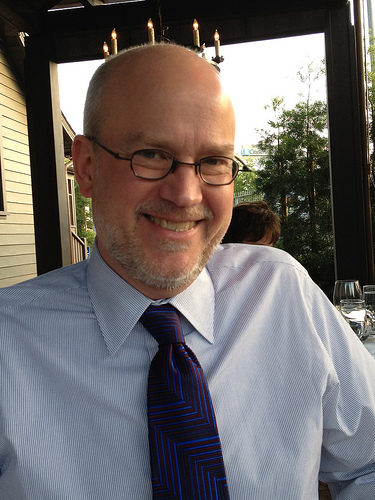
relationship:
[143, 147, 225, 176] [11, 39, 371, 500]
eyes of a man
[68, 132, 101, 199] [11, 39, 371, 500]
ear of a man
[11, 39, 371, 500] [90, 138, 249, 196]
man with glasses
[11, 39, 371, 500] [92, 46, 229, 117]
man with a bald head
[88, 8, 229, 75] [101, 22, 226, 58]
light fixture has candles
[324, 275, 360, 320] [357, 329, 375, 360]
water glass on table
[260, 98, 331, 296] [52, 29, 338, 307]
tree in background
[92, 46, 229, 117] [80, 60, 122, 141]
bald head with hair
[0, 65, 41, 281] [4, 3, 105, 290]
siding on building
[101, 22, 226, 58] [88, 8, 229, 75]
candles on light fixture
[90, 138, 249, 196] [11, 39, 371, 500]
glasses on man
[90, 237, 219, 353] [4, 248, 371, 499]
collar on shirt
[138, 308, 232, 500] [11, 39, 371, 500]
tie on man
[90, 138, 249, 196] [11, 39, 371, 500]
glasses of man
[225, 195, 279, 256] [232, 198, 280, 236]
woman has hair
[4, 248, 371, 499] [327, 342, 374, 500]
shirt has sleeves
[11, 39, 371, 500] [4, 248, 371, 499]
man has a shirt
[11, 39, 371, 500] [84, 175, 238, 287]
man has a beard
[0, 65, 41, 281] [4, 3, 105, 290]
siding of a building